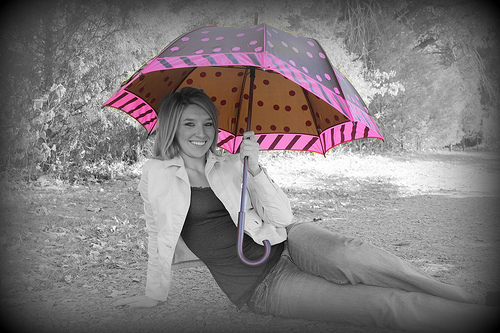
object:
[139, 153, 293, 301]
jacket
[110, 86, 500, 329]
girl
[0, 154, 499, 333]
ground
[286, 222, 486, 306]
legs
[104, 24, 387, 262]
umbrella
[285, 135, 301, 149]
stripes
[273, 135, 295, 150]
pink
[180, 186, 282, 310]
shirt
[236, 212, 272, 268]
handle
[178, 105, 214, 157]
face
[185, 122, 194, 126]
eye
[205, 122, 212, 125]
eye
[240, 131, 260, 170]
hand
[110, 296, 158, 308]
hand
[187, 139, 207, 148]
smile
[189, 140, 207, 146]
mouth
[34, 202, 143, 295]
leaves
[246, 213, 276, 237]
pocket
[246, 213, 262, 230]
flap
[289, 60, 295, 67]
dots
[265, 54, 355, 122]
edge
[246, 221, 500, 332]
pants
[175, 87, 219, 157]
head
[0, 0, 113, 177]
tree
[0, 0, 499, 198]
background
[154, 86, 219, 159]
hair